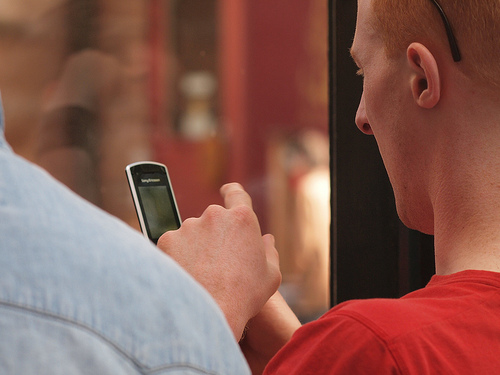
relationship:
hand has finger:
[154, 179, 284, 344] [219, 178, 253, 211]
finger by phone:
[219, 181, 250, 207] [124, 156, 182, 240]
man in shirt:
[156, 0, 498, 373] [261, 270, 498, 374]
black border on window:
[321, 0, 437, 318] [3, 0, 336, 374]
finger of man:
[209, 170, 263, 217] [156, 0, 498, 373]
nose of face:
[353, 90, 376, 140] [343, 62, 487, 230]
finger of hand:
[219, 181, 250, 207] [138, 164, 288, 371]